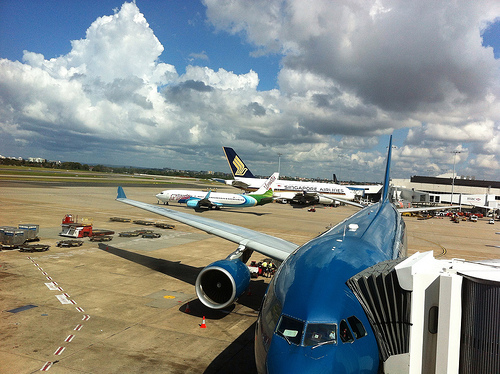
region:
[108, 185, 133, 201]
end of left wing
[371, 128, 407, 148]
top of plane tail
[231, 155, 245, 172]
yellow design on plane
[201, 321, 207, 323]
white strip on cone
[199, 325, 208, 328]
bottom of orange cone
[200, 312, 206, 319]
tip of orange cone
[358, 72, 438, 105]
dark clouds in sky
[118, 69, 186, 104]
white clouds in sky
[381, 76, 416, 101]
Dark clouds in sky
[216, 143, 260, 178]
yellow and black plane part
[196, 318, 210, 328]
orange and white cone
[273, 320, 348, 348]
front plane windows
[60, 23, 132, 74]
white clear clouds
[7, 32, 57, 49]
part of blue sky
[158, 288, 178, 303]
yellow spot on ground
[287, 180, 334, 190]
Black lettering on plane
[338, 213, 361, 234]
white part on top of plane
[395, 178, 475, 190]
tan building building with black over it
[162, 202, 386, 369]
blue plane at loading gate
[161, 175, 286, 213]
plane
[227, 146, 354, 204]
plane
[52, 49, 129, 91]
white clouds in blue sky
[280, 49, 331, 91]
white clouds in blue sky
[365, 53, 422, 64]
white clouds in blue sky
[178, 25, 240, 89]
white clouds in blue sky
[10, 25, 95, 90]
white clouds in blue sky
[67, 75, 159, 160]
white clouds in blue sky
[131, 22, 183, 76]
white clouds in blue sky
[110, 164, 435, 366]
A blue airplane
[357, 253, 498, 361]
A walkway connected to the plane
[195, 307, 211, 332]
An orange cone on the ground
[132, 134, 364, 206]
A pair of airplanes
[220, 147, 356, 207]
This airplane is owned by Singapore Airlines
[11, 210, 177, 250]
A bunch of flat carts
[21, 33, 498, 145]
Huge white clouds in the sky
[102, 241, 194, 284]
Shadow of the plane's wing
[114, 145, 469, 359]
The planes are at the airport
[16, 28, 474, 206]
Picture taken during daylight hours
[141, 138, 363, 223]
two planes on the tarmac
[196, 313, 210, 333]
orange and white cone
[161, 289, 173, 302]
small yellow circle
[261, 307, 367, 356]
windows around the cockpit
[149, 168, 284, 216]
white, blue, and green plane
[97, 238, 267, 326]
shadow from the wing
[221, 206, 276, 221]
shadow on the ground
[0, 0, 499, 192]
thick clouds in the sky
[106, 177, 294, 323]
jet engine under the wing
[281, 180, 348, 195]
writing on the side of the plane